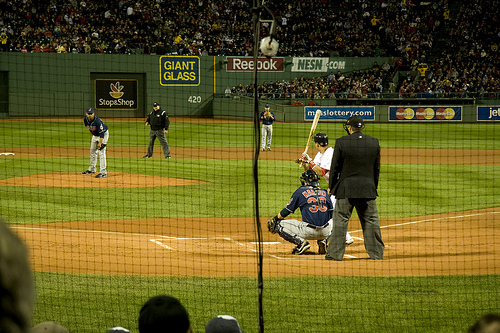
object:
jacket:
[323, 130, 385, 200]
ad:
[159, 52, 201, 87]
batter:
[297, 131, 358, 246]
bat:
[296, 107, 326, 168]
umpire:
[324, 117, 389, 262]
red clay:
[5, 170, 84, 187]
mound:
[3, 168, 213, 192]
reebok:
[221, 51, 289, 74]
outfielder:
[254, 99, 277, 150]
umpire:
[140, 102, 174, 160]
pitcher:
[80, 107, 110, 178]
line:
[3, 223, 181, 241]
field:
[1, 116, 500, 332]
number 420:
[186, 94, 202, 105]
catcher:
[269, 168, 336, 255]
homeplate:
[249, 238, 284, 246]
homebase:
[249, 228, 280, 248]